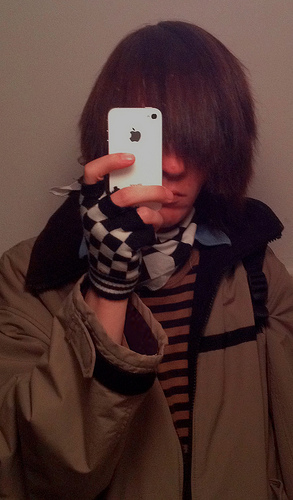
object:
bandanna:
[79, 208, 197, 293]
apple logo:
[129, 127, 141, 143]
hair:
[77, 20, 262, 209]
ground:
[232, 95, 253, 120]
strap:
[241, 255, 270, 332]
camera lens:
[151, 113, 157, 120]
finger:
[79, 153, 135, 203]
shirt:
[132, 249, 198, 452]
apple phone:
[106, 107, 163, 213]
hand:
[78, 152, 173, 285]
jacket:
[0, 189, 293, 500]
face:
[158, 139, 208, 228]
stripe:
[135, 249, 199, 453]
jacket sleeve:
[0, 272, 168, 498]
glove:
[78, 180, 155, 301]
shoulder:
[200, 215, 270, 308]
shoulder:
[0, 229, 76, 316]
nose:
[162, 146, 185, 177]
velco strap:
[62, 311, 97, 385]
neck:
[141, 224, 181, 286]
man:
[0, 20, 293, 500]